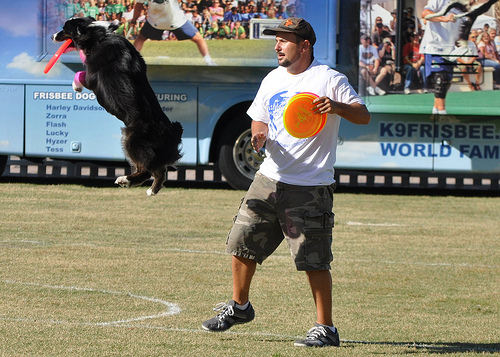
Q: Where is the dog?
A: Air.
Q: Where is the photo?
A: Grass field.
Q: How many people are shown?
A: 1.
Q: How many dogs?
A: 1.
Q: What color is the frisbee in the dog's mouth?
A: Orange.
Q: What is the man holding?
A: Frisbee.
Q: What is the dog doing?
A: Catching frisbee.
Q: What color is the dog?
A: Black.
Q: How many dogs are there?
A: 1.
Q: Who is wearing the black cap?
A: Man with the frisbee.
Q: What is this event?
A: K9 world frisbee competition.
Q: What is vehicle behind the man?
A: Rv.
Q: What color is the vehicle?
A: Blue.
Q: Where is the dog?
A: In the air.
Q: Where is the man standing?
A: Grass field.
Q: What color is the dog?
A: Black and white.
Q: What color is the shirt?
A: White.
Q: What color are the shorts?
A: Camo.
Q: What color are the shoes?
A: Black.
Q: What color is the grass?
A: Green.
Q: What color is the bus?
A: Blue.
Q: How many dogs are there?
A: One.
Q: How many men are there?
A: One.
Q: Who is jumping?
A: Dog.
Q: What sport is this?
A: K9 frisbee.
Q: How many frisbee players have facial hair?
A: 2.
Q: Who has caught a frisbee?
A: Dog.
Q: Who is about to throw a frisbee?
A: Man in camo shorts.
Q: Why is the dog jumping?
A: To catch the disk.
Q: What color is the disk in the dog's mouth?
A: Red.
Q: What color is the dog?
A: Black.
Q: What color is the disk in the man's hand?
A: Orange.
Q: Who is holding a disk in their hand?
A: The man.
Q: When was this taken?
A: Day time.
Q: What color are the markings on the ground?
A: White.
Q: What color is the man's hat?
A: Black.